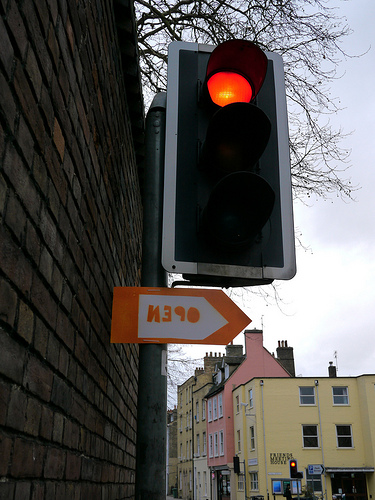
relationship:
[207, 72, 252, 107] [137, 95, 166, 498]
light on pole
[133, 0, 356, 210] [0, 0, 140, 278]
tree by wall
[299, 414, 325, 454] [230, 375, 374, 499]
small window on building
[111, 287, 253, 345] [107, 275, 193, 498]
arrow on pole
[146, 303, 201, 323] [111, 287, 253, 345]
writing on arrow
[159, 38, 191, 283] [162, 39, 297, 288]
border of sign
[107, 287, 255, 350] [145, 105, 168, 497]
arrow on pole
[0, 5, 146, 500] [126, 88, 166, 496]
wall next to pole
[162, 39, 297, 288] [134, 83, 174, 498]
sign on pole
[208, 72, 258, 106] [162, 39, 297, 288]
red light in sign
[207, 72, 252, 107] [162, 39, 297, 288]
light on sign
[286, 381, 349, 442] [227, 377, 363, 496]
window on building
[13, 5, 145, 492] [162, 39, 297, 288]
wall by sign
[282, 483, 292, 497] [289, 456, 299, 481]
person standing by traffic light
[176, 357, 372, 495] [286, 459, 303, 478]
building by traffic light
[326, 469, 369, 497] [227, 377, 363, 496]
doors on building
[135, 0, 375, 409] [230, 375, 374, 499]
sky above building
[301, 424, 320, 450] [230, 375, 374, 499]
small window on building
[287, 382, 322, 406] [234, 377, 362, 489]
small window on building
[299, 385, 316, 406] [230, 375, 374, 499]
small window on building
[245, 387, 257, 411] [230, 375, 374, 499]
window on building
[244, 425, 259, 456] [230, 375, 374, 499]
window on building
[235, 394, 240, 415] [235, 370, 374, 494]
window on building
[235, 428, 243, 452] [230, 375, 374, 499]
window on building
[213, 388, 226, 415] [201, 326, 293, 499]
window on building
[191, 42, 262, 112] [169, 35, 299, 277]
light on sign